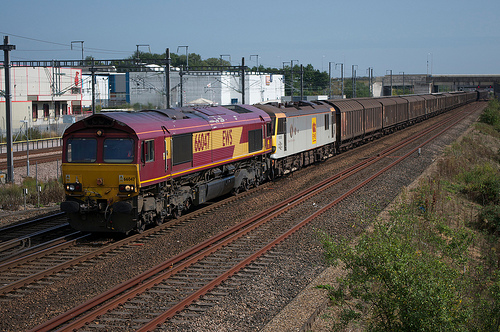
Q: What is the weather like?
A: It is clear.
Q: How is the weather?
A: It is clear.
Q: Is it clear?
A: Yes, it is clear.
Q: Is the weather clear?
A: Yes, it is clear.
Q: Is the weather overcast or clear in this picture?
A: It is clear.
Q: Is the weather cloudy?
A: No, it is clear.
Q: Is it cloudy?
A: No, it is clear.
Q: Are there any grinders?
A: No, there are no grinders.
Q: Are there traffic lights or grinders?
A: No, there are no grinders or traffic lights.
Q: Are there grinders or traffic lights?
A: No, there are no grinders or traffic lights.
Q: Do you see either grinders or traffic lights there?
A: No, there are no grinders or traffic lights.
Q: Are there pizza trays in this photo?
A: No, there are no pizza trays.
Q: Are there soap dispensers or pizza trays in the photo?
A: No, there are no pizza trays or soap dispensers.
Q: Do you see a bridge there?
A: Yes, there is a bridge.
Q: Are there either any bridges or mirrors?
A: Yes, there is a bridge.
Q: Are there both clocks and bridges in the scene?
A: No, there is a bridge but no clocks.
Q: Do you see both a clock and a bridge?
A: No, there is a bridge but no clocks.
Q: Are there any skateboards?
A: No, there are no skateboards.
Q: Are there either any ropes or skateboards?
A: No, there are no skateboards or ropes.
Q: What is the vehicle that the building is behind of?
A: The vehicle is a train.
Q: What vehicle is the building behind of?
A: The building is behind the train.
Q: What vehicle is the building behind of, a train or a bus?
A: The building is behind a train.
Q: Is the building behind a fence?
A: No, the building is behind the train.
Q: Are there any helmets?
A: No, there are no helmets.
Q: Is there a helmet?
A: No, there are no helmets.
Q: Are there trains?
A: Yes, there is a train.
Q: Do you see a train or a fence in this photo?
A: Yes, there is a train.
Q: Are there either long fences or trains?
A: Yes, there is a long train.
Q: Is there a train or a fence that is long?
A: Yes, the train is long.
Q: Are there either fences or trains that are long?
A: Yes, the train is long.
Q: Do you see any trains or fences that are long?
A: Yes, the train is long.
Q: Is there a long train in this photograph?
A: Yes, there is a long train.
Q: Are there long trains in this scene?
A: Yes, there is a long train.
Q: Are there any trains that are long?
A: Yes, there is a train that is long.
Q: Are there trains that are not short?
A: Yes, there is a long train.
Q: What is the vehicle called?
A: The vehicle is a train.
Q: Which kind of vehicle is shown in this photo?
A: The vehicle is a train.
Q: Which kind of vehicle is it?
A: The vehicle is a train.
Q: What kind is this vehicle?
A: This is a train.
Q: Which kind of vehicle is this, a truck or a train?
A: This is a train.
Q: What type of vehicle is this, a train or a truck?
A: This is a train.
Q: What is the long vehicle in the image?
A: The vehicle is a train.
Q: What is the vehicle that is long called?
A: The vehicle is a train.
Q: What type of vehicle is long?
A: The vehicle is a train.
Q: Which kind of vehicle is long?
A: The vehicle is a train.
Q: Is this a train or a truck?
A: This is a train.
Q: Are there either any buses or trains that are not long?
A: No, there is a train but it is long.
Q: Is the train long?
A: Yes, the train is long.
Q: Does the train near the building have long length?
A: Yes, the train is long.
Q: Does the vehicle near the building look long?
A: Yes, the train is long.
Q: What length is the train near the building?
A: The train is long.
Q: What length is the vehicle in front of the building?
A: The train is long.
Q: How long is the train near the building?
A: The train is long.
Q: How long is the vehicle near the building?
A: The train is long.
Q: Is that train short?
A: No, the train is long.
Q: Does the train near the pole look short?
A: No, the train is long.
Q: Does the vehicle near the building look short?
A: No, the train is long.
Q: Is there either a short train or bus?
A: No, there is a train but it is long.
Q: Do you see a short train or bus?
A: No, there is a train but it is long.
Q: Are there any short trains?
A: No, there is a train but it is long.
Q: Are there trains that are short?
A: No, there is a train but it is long.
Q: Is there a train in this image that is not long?
A: No, there is a train but it is long.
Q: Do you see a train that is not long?
A: No, there is a train but it is long.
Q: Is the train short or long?
A: The train is long.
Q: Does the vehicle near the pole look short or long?
A: The train is long.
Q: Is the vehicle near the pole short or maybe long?
A: The train is long.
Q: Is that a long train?
A: Yes, that is a long train.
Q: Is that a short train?
A: No, that is a long train.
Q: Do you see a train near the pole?
A: Yes, there is a train near the pole.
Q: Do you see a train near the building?
A: Yes, there is a train near the building.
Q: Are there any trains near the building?
A: Yes, there is a train near the building.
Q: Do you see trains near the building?
A: Yes, there is a train near the building.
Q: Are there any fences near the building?
A: No, there is a train near the building.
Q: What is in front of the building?
A: The train is in front of the building.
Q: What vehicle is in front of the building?
A: The vehicle is a train.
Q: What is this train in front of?
A: The train is in front of the building.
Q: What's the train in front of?
A: The train is in front of the building.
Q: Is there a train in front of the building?
A: Yes, there is a train in front of the building.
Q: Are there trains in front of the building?
A: Yes, there is a train in front of the building.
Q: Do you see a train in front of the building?
A: Yes, there is a train in front of the building.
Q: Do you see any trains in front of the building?
A: Yes, there is a train in front of the building.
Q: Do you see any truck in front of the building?
A: No, there is a train in front of the building.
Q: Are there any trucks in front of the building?
A: No, there is a train in front of the building.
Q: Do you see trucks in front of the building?
A: No, there is a train in front of the building.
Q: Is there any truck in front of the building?
A: No, there is a train in front of the building.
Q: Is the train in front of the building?
A: Yes, the train is in front of the building.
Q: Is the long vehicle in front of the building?
A: Yes, the train is in front of the building.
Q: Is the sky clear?
A: Yes, the sky is clear.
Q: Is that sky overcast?
A: No, the sky is clear.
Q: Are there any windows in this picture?
A: Yes, there are windows.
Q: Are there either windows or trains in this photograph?
A: Yes, there are windows.